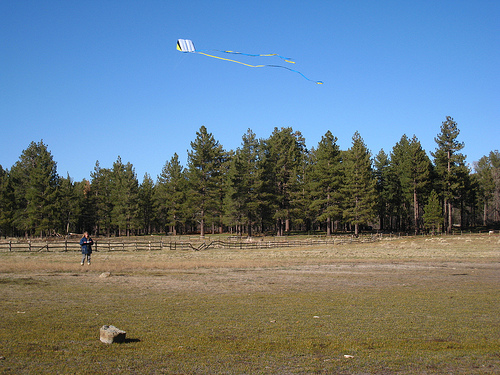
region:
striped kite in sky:
[155, 18, 345, 98]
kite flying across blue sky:
[159, 12, 346, 112]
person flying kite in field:
[46, 13, 371, 290]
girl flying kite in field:
[53, 18, 352, 283]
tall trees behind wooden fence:
[118, 91, 439, 260]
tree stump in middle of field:
[83, 305, 183, 365]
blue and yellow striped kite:
[152, 17, 339, 102]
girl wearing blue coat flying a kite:
[59, 15, 361, 280]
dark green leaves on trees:
[215, 116, 390, 248]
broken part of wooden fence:
[165, 235, 297, 270]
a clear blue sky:
[2, 0, 499, 174]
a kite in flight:
[174, 33, 324, 85]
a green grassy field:
[2, 237, 494, 372]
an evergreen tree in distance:
[23, 142, 58, 236]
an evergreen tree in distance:
[12, 140, 30, 231]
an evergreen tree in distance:
[54, 171, 81, 231]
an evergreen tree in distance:
[82, 159, 107, 226]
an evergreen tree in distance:
[108, 159, 142, 231]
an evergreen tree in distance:
[137, 170, 155, 233]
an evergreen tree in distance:
[152, 153, 189, 227]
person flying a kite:
[64, 30, 326, 271]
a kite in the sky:
[165, 25, 332, 93]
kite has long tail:
[170, 28, 335, 91]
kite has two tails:
[170, 29, 336, 90]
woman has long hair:
[74, 225, 99, 271]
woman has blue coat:
[71, 226, 103, 268]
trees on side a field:
[1, 113, 481, 237]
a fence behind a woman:
[0, 227, 487, 255]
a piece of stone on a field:
[91, 314, 131, 351]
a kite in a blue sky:
[6, 5, 498, 121]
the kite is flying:
[151, 22, 374, 122]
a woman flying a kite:
[41, 34, 358, 301]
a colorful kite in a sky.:
[169, 28, 209, 63]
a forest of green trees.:
[0, 112, 498, 231]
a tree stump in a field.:
[75, 311, 137, 359]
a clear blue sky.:
[0, 0, 497, 185]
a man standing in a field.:
[74, 223, 99, 273]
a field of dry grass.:
[0, 228, 494, 289]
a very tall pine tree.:
[430, 100, 466, 234]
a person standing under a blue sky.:
[79, 223, 101, 264]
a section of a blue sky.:
[46, 29, 133, 96]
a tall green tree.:
[6, 133, 63, 241]